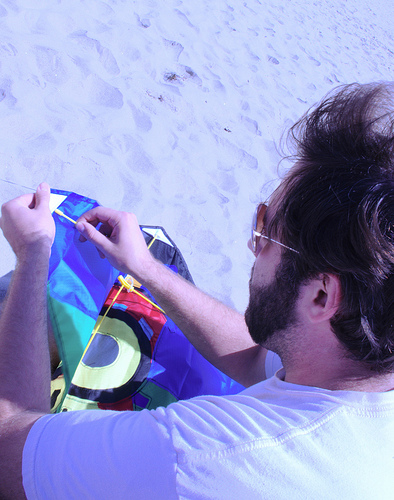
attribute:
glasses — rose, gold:
[244, 194, 353, 285]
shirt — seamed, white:
[18, 371, 393, 499]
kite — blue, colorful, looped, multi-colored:
[17, 182, 245, 427]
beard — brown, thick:
[241, 258, 305, 353]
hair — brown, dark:
[276, 77, 393, 361]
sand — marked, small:
[0, 1, 393, 323]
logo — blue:
[71, 293, 155, 407]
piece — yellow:
[52, 201, 76, 233]